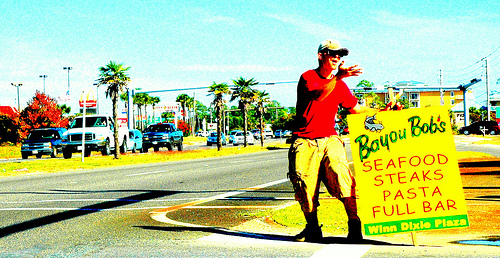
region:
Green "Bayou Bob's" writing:
[354, 114, 452, 165]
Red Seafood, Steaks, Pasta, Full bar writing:
[357, 152, 458, 218]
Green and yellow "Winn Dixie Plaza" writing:
[361, 213, 483, 239]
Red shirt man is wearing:
[285, 68, 361, 147]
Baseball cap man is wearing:
[311, 32, 349, 54]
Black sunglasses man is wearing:
[315, 49, 350, 59]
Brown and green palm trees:
[92, 57, 289, 164]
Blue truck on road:
[140, 117, 188, 157]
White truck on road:
[60, 107, 131, 161]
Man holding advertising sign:
[280, 33, 371, 255]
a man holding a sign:
[280, 37, 466, 256]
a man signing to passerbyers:
[283, 27, 475, 256]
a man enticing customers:
[274, 30, 467, 253]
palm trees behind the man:
[206, 71, 271, 146]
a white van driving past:
[66, 107, 121, 156]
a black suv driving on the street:
[20, 123, 66, 162]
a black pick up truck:
[142, 117, 199, 167]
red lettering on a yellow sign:
[366, 163, 449, 215]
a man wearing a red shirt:
[262, 37, 356, 222]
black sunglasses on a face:
[321, 45, 352, 60]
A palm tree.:
[98, 49, 135, 173]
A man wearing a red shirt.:
[296, 37, 362, 247]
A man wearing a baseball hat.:
[288, 33, 350, 256]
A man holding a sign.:
[276, 40, 470, 240]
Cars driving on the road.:
[21, 107, 184, 169]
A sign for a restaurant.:
[344, 104, 478, 251]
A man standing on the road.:
[257, 30, 378, 253]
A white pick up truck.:
[64, 107, 134, 157]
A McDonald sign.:
[68, 82, 108, 110]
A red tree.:
[13, 84, 70, 171]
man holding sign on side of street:
[234, 38, 442, 250]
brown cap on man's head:
[308, 35, 356, 57]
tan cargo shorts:
[268, 135, 355, 242]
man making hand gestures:
[264, 33, 379, 244]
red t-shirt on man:
[281, 73, 363, 140]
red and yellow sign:
[344, 105, 465, 250]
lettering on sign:
[314, 92, 471, 242]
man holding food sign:
[284, 26, 489, 248]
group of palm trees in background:
[181, 66, 266, 151]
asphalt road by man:
[14, 149, 245, 256]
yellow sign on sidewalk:
[340, 100, 475, 239]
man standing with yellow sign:
[292, 40, 349, 246]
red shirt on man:
[296, 64, 352, 145]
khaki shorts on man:
[294, 138, 356, 204]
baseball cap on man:
[320, 38, 345, 55]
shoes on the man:
[297, 213, 327, 253]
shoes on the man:
[344, 213, 366, 246]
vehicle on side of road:
[77, 108, 117, 153]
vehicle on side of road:
[151, 124, 193, 166]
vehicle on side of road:
[21, 123, 70, 161]